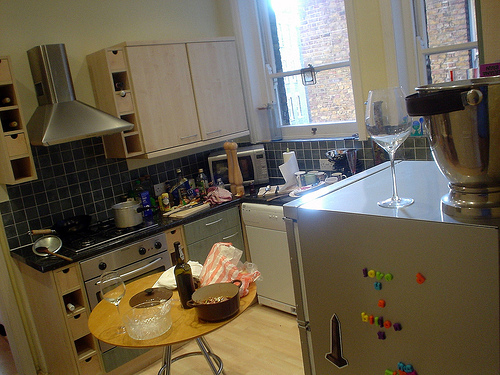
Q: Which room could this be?
A: It is a kitchen.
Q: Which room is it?
A: It is a kitchen.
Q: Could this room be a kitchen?
A: Yes, it is a kitchen.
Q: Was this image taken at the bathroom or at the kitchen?
A: It was taken at the kitchen.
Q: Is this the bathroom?
A: No, it is the kitchen.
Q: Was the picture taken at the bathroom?
A: No, the picture was taken in the kitchen.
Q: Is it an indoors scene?
A: Yes, it is indoors.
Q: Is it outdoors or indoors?
A: It is indoors.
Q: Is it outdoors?
A: No, it is indoors.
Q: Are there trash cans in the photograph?
A: No, there are no trash cans.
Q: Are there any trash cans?
A: No, there are no trash cans.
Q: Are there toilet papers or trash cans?
A: No, there are no trash cans or toilet papers.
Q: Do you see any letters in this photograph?
A: Yes, there are letters.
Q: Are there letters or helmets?
A: Yes, there are letters.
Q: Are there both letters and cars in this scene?
A: No, there are letters but no cars.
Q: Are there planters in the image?
A: No, there are no planters.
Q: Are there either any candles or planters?
A: No, there are no planters or candles.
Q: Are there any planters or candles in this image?
A: No, there are no planters or candles.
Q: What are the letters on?
A: The letters are on the fridge.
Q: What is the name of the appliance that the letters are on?
A: The appliance is a refrigerator.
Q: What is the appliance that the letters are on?
A: The appliance is a refrigerator.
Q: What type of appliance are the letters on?
A: The letters are on the freezer.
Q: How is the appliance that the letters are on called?
A: The appliance is a refrigerator.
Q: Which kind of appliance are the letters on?
A: The letters are on the freezer.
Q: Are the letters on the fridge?
A: Yes, the letters are on the fridge.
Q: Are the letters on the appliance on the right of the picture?
A: Yes, the letters are on the fridge.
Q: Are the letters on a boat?
A: No, the letters are on the fridge.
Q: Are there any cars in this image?
A: No, there are no cars.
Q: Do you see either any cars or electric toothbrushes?
A: No, there are no cars or electric toothbrushes.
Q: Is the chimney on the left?
A: Yes, the chimney is on the left of the image.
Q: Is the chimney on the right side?
A: No, the chimney is on the left of the image.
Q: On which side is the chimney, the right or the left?
A: The chimney is on the left of the image.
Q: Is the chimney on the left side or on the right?
A: The chimney is on the left of the image.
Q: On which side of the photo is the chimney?
A: The chimney is on the left of the image.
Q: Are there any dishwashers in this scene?
A: Yes, there is a dishwasher.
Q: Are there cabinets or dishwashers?
A: Yes, there is a dishwasher.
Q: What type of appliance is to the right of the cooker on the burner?
A: The appliance is a dishwasher.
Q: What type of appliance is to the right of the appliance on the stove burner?
A: The appliance is a dishwasher.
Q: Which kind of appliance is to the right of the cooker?
A: The appliance is a dishwasher.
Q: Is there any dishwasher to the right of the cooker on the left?
A: Yes, there is a dishwasher to the right of the cooker.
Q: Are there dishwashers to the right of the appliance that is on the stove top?
A: Yes, there is a dishwasher to the right of the cooker.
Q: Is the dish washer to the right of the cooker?
A: Yes, the dish washer is to the right of the cooker.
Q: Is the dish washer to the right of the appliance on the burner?
A: Yes, the dish washer is to the right of the cooker.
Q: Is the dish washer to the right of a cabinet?
A: No, the dish washer is to the right of the cooker.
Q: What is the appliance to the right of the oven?
A: The appliance is a dishwasher.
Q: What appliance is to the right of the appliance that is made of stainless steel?
A: The appliance is a dishwasher.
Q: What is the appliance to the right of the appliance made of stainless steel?
A: The appliance is a dishwasher.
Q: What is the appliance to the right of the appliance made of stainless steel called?
A: The appliance is a dishwasher.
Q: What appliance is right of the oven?
A: The appliance is a dishwasher.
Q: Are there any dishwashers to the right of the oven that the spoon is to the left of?
A: Yes, there is a dishwasher to the right of the oven.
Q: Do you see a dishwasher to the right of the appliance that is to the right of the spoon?
A: Yes, there is a dishwasher to the right of the oven.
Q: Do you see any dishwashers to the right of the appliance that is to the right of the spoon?
A: Yes, there is a dishwasher to the right of the oven.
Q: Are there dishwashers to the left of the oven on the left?
A: No, the dishwasher is to the right of the oven.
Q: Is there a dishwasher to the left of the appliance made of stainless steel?
A: No, the dishwasher is to the right of the oven.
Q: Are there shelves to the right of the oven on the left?
A: No, there is a dishwasher to the right of the oven.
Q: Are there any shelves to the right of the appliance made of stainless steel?
A: No, there is a dishwasher to the right of the oven.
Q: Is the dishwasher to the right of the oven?
A: Yes, the dishwasher is to the right of the oven.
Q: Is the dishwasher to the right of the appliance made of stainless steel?
A: Yes, the dishwasher is to the right of the oven.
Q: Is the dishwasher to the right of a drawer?
A: No, the dishwasher is to the right of the oven.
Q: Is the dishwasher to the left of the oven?
A: No, the dishwasher is to the right of the oven.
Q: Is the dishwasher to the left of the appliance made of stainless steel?
A: No, the dishwasher is to the right of the oven.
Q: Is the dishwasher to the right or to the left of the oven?
A: The dishwasher is to the right of the oven.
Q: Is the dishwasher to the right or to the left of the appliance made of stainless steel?
A: The dishwasher is to the right of the oven.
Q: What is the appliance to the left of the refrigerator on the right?
A: The appliance is a dishwasher.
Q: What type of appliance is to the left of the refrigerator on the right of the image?
A: The appliance is a dishwasher.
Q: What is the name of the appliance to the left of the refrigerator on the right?
A: The appliance is a dishwasher.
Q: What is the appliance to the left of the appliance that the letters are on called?
A: The appliance is a dishwasher.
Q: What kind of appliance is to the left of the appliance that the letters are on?
A: The appliance is a dishwasher.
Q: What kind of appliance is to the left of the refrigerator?
A: The appliance is a dishwasher.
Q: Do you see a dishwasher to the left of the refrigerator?
A: Yes, there is a dishwasher to the left of the refrigerator.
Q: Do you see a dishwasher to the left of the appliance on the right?
A: Yes, there is a dishwasher to the left of the refrigerator.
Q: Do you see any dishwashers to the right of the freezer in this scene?
A: No, the dishwasher is to the left of the freezer.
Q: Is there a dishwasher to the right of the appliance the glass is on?
A: No, the dishwasher is to the left of the freezer.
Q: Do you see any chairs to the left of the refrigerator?
A: No, there is a dishwasher to the left of the refrigerator.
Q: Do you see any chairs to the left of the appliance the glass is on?
A: No, there is a dishwasher to the left of the refrigerator.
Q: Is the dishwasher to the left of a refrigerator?
A: Yes, the dishwasher is to the left of a refrigerator.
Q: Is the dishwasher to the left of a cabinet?
A: No, the dishwasher is to the left of a refrigerator.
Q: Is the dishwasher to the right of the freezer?
A: No, the dishwasher is to the left of the freezer.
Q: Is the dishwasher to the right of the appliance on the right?
A: No, the dishwasher is to the left of the freezer.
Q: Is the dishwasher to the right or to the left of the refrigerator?
A: The dishwasher is to the left of the refrigerator.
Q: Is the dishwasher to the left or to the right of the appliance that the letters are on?
A: The dishwasher is to the left of the refrigerator.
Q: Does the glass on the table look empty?
A: Yes, the glass is empty.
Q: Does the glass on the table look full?
A: No, the glass is empty.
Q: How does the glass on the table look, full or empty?
A: The glass is empty.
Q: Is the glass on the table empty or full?
A: The glass is empty.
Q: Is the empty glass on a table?
A: Yes, the glass is on a table.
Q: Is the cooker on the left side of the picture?
A: Yes, the cooker is on the left of the image.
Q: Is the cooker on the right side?
A: No, the cooker is on the left of the image.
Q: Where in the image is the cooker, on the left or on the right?
A: The cooker is on the left of the image.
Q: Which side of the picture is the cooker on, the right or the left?
A: The cooker is on the left of the image.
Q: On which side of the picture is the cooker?
A: The cooker is on the left of the image.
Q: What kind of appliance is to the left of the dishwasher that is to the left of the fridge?
A: The appliance is a cooker.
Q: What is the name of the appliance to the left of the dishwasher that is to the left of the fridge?
A: The appliance is a cooker.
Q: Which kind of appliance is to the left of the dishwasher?
A: The appliance is a cooker.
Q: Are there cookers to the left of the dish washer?
A: Yes, there is a cooker to the left of the dish washer.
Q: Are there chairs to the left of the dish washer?
A: No, there is a cooker to the left of the dish washer.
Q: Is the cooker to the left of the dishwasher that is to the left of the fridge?
A: Yes, the cooker is to the left of the dish washer.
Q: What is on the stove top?
A: The cooker is on the stove top.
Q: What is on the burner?
A: The cooker is on the stove top.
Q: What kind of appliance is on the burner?
A: The appliance is a cooker.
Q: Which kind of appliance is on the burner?
A: The appliance is a cooker.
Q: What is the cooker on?
A: The cooker is on the burner.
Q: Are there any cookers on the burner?
A: Yes, there is a cooker on the burner.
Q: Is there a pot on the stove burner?
A: No, there is a cooker on the stove burner.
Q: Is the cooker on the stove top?
A: Yes, the cooker is on the stove top.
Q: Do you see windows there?
A: Yes, there is a window.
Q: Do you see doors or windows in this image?
A: Yes, there is a window.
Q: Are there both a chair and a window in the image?
A: No, there is a window but no chairs.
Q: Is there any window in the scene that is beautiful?
A: Yes, there is a beautiful window.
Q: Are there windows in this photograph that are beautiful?
A: Yes, there is a window that is beautiful.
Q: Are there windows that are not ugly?
A: Yes, there is an beautiful window.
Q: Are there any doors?
A: No, there are no doors.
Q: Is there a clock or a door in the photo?
A: No, there are no doors or clocks.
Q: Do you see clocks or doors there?
A: No, there are no doors or clocks.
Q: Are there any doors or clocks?
A: No, there are no doors or clocks.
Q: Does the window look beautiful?
A: Yes, the window is beautiful.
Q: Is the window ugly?
A: No, the window is beautiful.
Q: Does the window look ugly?
A: No, the window is beautiful.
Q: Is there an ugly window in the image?
A: No, there is a window but it is beautiful.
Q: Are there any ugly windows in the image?
A: No, there is a window but it is beautiful.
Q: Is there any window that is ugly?
A: No, there is a window but it is beautiful.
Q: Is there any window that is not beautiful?
A: No, there is a window but it is beautiful.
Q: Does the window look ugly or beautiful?
A: The window is beautiful.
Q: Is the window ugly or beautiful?
A: The window is beautiful.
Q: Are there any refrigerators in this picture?
A: Yes, there is a refrigerator.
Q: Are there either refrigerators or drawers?
A: Yes, there is a refrigerator.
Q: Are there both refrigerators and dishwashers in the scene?
A: Yes, there are both a refrigerator and a dishwasher.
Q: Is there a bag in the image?
A: No, there are no bags.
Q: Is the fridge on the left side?
A: No, the fridge is on the right of the image.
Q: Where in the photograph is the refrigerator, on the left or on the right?
A: The refrigerator is on the right of the image.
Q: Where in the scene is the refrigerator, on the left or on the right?
A: The refrigerator is on the right of the image.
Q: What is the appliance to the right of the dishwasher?
A: The appliance is a refrigerator.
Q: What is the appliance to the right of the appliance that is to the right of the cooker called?
A: The appliance is a refrigerator.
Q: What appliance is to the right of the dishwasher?
A: The appliance is a refrigerator.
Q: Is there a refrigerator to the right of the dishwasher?
A: Yes, there is a refrigerator to the right of the dishwasher.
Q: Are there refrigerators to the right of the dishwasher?
A: Yes, there is a refrigerator to the right of the dishwasher.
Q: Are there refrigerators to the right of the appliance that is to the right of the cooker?
A: Yes, there is a refrigerator to the right of the dishwasher.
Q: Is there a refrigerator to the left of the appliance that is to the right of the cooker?
A: No, the refrigerator is to the right of the dishwasher.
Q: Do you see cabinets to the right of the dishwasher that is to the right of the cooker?
A: No, there is a refrigerator to the right of the dish washer.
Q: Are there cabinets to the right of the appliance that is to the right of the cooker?
A: No, there is a refrigerator to the right of the dish washer.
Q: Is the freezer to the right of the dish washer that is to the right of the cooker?
A: Yes, the freezer is to the right of the dishwasher.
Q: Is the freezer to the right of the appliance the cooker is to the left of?
A: Yes, the freezer is to the right of the dishwasher.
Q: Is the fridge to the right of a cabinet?
A: No, the fridge is to the right of the dishwasher.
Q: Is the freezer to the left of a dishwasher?
A: No, the freezer is to the right of a dishwasher.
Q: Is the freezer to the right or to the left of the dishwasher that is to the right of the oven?
A: The freezer is to the right of the dishwasher.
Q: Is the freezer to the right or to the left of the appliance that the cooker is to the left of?
A: The freezer is to the right of the dishwasher.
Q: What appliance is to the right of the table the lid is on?
A: The appliance is a refrigerator.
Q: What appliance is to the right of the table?
A: The appliance is a refrigerator.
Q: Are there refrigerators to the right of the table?
A: Yes, there is a refrigerator to the right of the table.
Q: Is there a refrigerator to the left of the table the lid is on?
A: No, the refrigerator is to the right of the table.